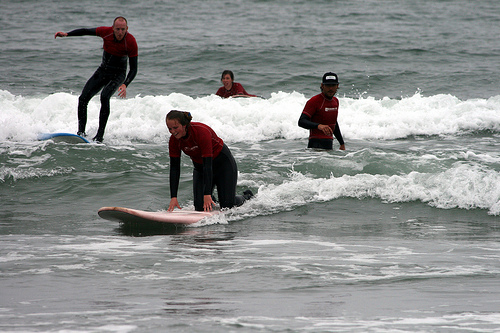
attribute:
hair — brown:
[220, 65, 235, 80]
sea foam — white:
[1, 88, 497, 143]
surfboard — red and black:
[98, 193, 310, 244]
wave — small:
[18, 103, 155, 181]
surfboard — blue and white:
[37, 131, 91, 143]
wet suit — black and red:
[64, 25, 139, 139]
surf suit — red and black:
[58, 26, 140, 138]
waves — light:
[325, 2, 498, 262]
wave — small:
[6, 77, 491, 169]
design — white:
[322, 72, 336, 83]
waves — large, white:
[0, 88, 498, 143]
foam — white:
[7, 87, 496, 165]